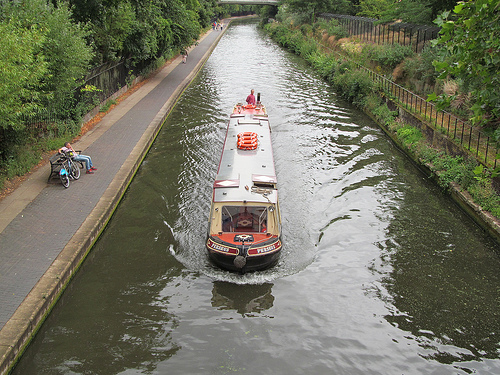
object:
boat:
[203, 93, 284, 274]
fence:
[312, 9, 439, 60]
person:
[219, 21, 223, 30]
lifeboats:
[238, 136, 257, 144]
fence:
[267, 17, 500, 172]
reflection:
[211, 280, 272, 322]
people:
[213, 22, 218, 30]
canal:
[10, 17, 497, 373]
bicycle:
[55, 150, 80, 189]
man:
[58, 142, 97, 174]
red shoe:
[90, 165, 97, 170]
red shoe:
[85, 169, 94, 174]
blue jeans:
[73, 154, 93, 169]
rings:
[237, 140, 258, 147]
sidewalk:
[0, 12, 262, 375]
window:
[222, 205, 268, 232]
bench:
[47, 145, 84, 184]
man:
[246, 88, 256, 106]